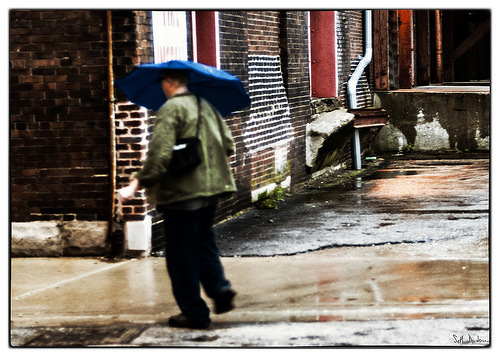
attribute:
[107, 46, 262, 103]
umbrella — open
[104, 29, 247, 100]
umbrella — open, blue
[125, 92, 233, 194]
jacket — green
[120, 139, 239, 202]
purse — black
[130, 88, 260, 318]
woman — black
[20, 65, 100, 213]
wall — red, brick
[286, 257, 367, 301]
sidewalk — rain soaked, red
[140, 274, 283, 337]
shoe — black 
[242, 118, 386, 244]
plant — small 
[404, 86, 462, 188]
patch — white 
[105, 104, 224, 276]
bag — black 